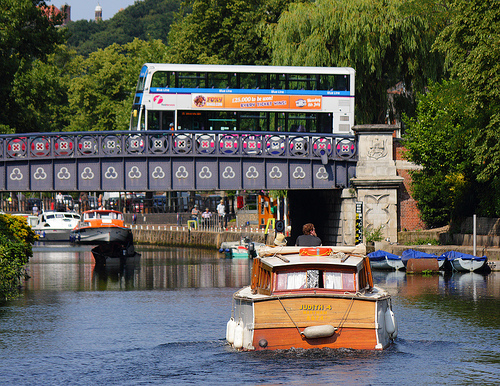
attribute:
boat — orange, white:
[217, 238, 398, 353]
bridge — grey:
[3, 126, 355, 197]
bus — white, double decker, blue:
[126, 56, 356, 142]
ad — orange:
[195, 95, 322, 112]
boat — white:
[29, 206, 75, 242]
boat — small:
[442, 248, 488, 274]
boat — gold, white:
[73, 205, 135, 246]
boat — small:
[399, 247, 442, 277]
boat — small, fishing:
[367, 248, 406, 271]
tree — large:
[395, 20, 498, 236]